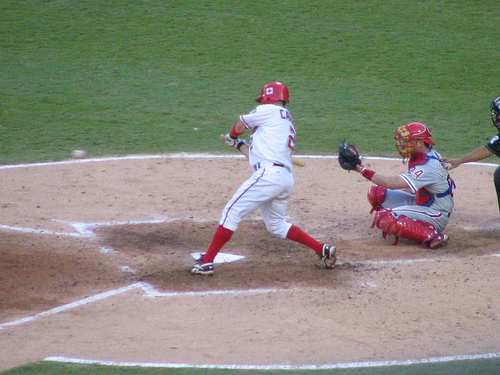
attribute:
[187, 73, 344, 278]
man — batter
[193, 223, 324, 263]
socks — red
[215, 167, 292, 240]
pants — white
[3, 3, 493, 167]
grass — green, lush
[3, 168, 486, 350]
ground — dirt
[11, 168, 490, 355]
dirt — brown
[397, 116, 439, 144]
helmet — Red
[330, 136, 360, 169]
mitt — black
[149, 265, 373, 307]
lines — white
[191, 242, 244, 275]
base — white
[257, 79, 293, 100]
helmet — red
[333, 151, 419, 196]
arm — extended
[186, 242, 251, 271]
white plate — rubber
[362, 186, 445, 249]
leg guards — red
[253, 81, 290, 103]
red helmet — bright red, shiny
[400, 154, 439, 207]
red vest — blue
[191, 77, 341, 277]
batter in uniform — white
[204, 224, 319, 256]
red socks — long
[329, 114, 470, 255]
catcher uniform — grey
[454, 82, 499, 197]
baseball umpire — black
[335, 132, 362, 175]
mitt — black, leather